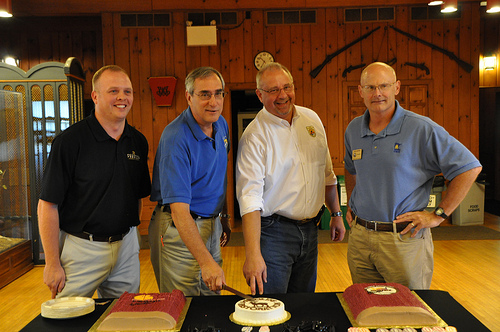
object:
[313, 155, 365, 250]
trash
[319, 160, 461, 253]
recycle bins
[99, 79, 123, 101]
eye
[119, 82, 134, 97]
eye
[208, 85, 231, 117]
eye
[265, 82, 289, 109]
eye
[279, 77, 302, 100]
eye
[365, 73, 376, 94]
eye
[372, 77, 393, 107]
eye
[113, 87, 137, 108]
eye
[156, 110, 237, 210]
shirt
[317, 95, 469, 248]
shirt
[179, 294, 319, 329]
table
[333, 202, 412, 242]
belt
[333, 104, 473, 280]
man's shirt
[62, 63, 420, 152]
men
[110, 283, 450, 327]
cakes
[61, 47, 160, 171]
man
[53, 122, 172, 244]
shirt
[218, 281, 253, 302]
knife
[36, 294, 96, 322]
plates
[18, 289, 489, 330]
table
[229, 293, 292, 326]
cake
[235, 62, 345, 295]
guy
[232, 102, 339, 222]
shirt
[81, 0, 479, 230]
wall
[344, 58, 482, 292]
man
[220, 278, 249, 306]
utensil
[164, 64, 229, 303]
man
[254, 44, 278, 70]
clock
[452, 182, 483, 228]
can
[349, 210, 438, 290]
khakis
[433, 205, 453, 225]
watch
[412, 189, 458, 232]
wrist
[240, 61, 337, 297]
man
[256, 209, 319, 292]
jeans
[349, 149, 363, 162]
tag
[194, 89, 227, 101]
glasses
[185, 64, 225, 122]
face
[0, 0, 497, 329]
building